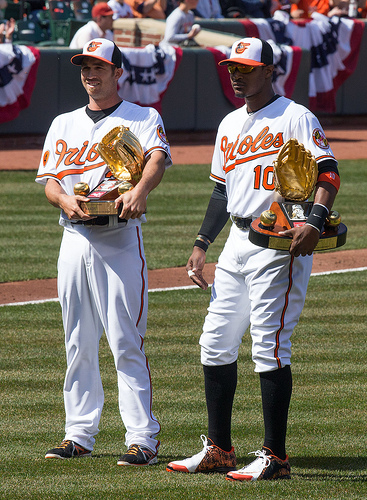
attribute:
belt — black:
[76, 196, 120, 219]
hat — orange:
[214, 34, 275, 75]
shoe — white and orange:
[167, 444, 239, 473]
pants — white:
[64, 238, 200, 353]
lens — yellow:
[236, 62, 252, 72]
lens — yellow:
[226, 63, 237, 72]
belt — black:
[70, 214, 127, 227]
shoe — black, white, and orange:
[222, 444, 296, 484]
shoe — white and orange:
[225, 447, 296, 486]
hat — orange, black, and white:
[65, 28, 128, 70]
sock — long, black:
[255, 365, 295, 454]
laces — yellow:
[122, 444, 138, 456]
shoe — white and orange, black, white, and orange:
[163, 432, 239, 476]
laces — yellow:
[53, 436, 75, 450]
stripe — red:
[133, 220, 165, 460]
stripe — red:
[273, 250, 297, 367]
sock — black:
[260, 361, 292, 457]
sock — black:
[205, 359, 239, 453]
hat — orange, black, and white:
[219, 34, 276, 70]